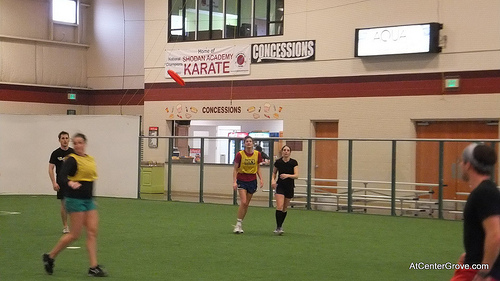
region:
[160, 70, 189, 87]
red frisbee in the air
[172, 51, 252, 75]
white and red sign on wall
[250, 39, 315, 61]
black and white sign on wall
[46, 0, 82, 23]
window on the wall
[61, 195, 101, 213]
blue shorts on the woman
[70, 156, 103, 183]
yellow shirt on the woman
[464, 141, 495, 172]
gray headband on man's head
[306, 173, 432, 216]
bleachers behind the fence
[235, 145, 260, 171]
yellow tank top on man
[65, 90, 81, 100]
a gray and green exit sign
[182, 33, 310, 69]
signs on the wall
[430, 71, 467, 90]
exit sign on wall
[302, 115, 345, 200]
door on the wall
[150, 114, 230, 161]
window on the wall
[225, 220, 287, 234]
shoes of the women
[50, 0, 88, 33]
window on th wall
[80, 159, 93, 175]
yellow on the shirt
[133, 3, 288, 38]
window on the wall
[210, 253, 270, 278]
green on the floor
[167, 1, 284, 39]
black windows on a building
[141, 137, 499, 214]
a metal fence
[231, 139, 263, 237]
a man running toward a man wearing a black shirt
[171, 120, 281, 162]
window to a concession stand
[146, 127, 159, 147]
a white panel on the wall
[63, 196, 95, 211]
woman wearing green shorts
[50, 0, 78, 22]
a window on a white wall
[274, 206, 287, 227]
woman wearing black socks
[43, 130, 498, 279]
people standing and running on an indoor field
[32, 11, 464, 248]
this an indoor sports arena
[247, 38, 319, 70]
the sign says "Concessions"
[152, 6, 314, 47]
this is a window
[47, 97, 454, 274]
they are playing a sport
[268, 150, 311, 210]
this player is wearing black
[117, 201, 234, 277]
this is soccer turf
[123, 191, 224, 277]
the turf is short and green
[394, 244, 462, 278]
there is a website watermark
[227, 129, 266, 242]
this is a person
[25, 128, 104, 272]
this is a person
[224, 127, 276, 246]
this is a person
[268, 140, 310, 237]
this is a person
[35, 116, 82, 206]
this is a person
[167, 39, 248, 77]
this is a sign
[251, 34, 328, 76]
this is a sign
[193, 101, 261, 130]
this is a sign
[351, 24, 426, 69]
this is a sign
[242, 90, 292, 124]
this is a sign